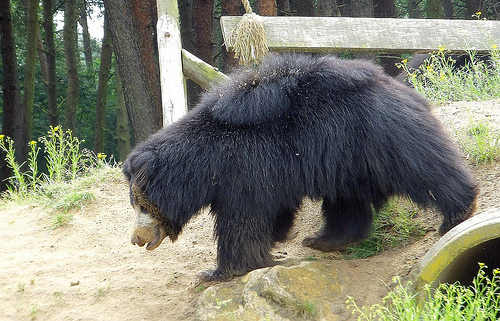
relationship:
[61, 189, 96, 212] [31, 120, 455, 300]
patch of grass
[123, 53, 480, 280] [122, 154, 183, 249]
bear has face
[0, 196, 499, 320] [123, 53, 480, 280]
sand under bear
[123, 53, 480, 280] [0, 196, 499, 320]
bear on sand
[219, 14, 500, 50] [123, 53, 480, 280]
board behind bear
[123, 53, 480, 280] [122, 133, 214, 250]
bear has head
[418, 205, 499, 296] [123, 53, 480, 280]
tunnel by bear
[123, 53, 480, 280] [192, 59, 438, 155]
bear has back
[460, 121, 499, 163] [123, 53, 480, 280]
shrubs by bear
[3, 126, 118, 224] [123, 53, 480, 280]
plants by bear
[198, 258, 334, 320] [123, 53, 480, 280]
rocks by bear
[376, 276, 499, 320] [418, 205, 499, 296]
plants by tunnel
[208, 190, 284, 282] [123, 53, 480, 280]
legs on bear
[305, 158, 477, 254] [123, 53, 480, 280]
legs on bear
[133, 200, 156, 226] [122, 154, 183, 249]
patch on face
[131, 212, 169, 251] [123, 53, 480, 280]
snout on bear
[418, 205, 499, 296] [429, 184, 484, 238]
pipe under foot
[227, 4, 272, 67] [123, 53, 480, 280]
rope over bear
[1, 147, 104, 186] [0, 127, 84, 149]
stems on flowers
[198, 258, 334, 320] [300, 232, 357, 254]
rocks under paw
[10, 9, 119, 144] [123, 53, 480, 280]
trees behind bear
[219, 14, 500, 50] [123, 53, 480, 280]
wood near bear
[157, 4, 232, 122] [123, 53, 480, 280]
plank near bear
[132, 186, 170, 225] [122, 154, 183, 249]
dirt on face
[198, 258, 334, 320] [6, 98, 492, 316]
rocks in path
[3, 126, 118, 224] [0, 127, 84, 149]
plants have flowers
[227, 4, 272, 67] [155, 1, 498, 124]
rope on fence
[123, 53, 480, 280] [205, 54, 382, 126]
bear with fur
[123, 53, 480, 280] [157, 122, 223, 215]
bear bends neck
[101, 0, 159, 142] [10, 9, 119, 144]
bark on trees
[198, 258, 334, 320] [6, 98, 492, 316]
rocks on ground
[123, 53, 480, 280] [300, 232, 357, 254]
bear has paw